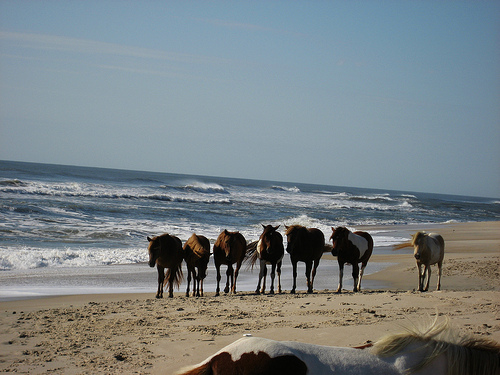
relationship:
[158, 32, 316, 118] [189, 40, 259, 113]
sky has clouds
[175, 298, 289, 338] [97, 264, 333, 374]
sand has tracks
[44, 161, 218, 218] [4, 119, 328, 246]
waves in ocean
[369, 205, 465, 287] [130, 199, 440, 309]
horse in front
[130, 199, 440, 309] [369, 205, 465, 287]
line of horse